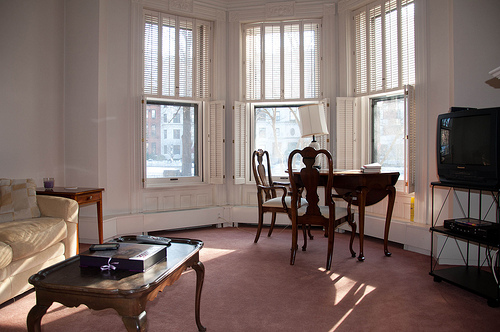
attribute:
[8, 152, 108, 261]
couch — beige, white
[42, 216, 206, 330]
table — brown, vintage, wooden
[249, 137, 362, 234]
chairs — brown, wooden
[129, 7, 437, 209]
window — open, closed, white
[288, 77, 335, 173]
lamp — white, ceramic, titled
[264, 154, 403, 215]
table — wooden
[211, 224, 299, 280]
carpet — red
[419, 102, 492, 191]
tv — old, black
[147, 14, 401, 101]
shutters — white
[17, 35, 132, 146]
walls — white